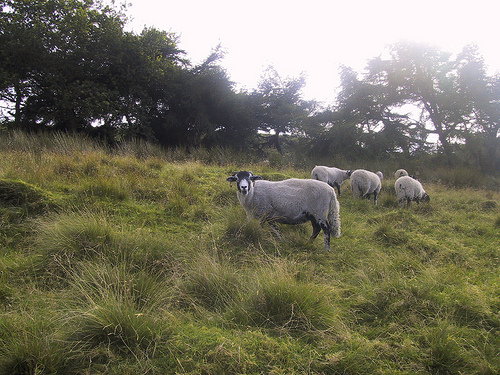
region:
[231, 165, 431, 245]
six sheep in a pasture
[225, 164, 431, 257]
white and black sheep on farmland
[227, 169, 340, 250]
a white and black sheep standing on a hill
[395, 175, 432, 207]
a sheep eating tall grass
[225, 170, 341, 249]
a sheep looking in the direction of the cameraman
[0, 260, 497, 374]
tall grass and weeds on the ground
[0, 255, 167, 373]
brown and green wild grass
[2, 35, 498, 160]
trees with green leaves on the farmland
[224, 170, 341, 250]
a sheep standing in front of other sheep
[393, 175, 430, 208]
a sheep grazing in a pasture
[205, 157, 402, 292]
this sheep is facinated with the camera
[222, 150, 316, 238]
her face is mostly black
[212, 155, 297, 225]
her snout is white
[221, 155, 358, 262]
her tail is rather long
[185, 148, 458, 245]
the rest of the herd is grazing quietly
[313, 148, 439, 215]
the rest of the herd seems undisturbed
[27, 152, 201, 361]
the meadow is lush with grasses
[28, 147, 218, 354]
this appears to be a great place to graze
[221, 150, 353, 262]
the sheep seems to be posing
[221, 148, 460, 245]
the sheep have heavy coats - they have not been shorn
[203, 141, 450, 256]
sheep on the grass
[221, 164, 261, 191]
black and white head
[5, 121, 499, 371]
field of long green grass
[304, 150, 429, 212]
three sheep showing their backsides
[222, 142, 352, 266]
side profile of a sheep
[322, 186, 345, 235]
fluffy white tail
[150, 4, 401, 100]
light shining over the tree tops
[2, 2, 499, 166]
green trees along the field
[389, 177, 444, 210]
sheep grazing in the grass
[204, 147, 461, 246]
herd of sheep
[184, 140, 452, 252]
a flock of sheep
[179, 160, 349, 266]
this sheep has a long tail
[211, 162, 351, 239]
she also has a black & white face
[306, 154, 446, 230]
the other sheep are in the background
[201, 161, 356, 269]
this sheep is staring at the camera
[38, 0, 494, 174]
trees are in the background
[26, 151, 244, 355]
the land appears to have a lot of grazing area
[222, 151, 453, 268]
it appears to be five or six sheep in the photo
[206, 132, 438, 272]
the sheep have not been shorn yet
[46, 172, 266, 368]
the grass & weeds are very thick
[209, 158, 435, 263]
@ least six sheep but only one is looking @ us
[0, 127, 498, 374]
bushy, sticky green weeds+grass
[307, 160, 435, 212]
four, maybe five, conspicuous rumpus rooms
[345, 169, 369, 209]
a butt end turned away has a long matty tail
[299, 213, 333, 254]
engaged sheep has marbled hind legs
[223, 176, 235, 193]
attentive sheep has ear tag, right ear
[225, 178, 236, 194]
ear tag, right ear, hangs like a pirate's [or, in truth, like an old rocker's]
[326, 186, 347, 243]
long fluffy tail of our observant sheep looks like wool flower garland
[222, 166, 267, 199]
white hide around the dark eyes in a white+black face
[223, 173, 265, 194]
black horizontal ears lead outward from sheephead